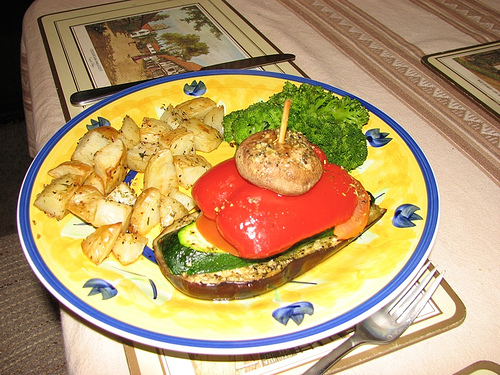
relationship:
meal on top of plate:
[34, 83, 387, 301] [17, 69, 440, 356]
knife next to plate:
[69, 53, 296, 109] [17, 69, 440, 356]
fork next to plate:
[304, 258, 447, 372] [17, 69, 440, 356]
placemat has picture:
[37, 5, 311, 124] [84, 5, 245, 86]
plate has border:
[17, 69, 440, 356] [19, 74, 441, 350]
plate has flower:
[17, 69, 440, 356] [185, 80, 206, 97]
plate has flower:
[17, 69, 440, 356] [367, 129, 392, 148]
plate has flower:
[17, 69, 440, 356] [394, 204, 423, 229]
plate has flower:
[17, 69, 440, 356] [274, 302, 315, 329]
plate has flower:
[17, 69, 440, 356] [84, 277, 119, 302]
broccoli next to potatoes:
[224, 81, 371, 173] [35, 97, 224, 268]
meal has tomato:
[34, 83, 387, 301] [196, 210, 240, 259]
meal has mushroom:
[34, 83, 387, 301] [234, 127, 323, 196]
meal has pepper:
[34, 83, 387, 301] [192, 144, 358, 261]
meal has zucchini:
[34, 83, 387, 301] [157, 219, 335, 278]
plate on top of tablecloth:
[17, 69, 440, 356] [22, 5, 497, 370]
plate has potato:
[17, 69, 440, 356] [176, 97, 219, 122]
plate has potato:
[17, 69, 440, 356] [139, 119, 172, 145]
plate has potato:
[17, 69, 440, 356] [144, 150, 179, 198]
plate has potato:
[17, 69, 440, 356] [92, 139, 129, 198]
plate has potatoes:
[17, 69, 440, 356] [80, 221, 123, 265]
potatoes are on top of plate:
[35, 97, 224, 268] [17, 69, 440, 356]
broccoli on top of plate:
[224, 81, 371, 173] [17, 69, 440, 356]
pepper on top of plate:
[192, 144, 358, 261] [17, 69, 440, 356]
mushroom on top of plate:
[234, 127, 323, 196] [17, 69, 440, 356]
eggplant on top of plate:
[152, 210, 387, 300] [17, 69, 440, 356]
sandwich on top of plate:
[154, 129, 388, 303] [17, 69, 440, 356]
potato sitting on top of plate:
[176, 97, 219, 122] [17, 69, 440, 356]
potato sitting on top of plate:
[139, 119, 172, 145] [17, 69, 440, 356]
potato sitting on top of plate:
[71, 122, 121, 168] [17, 69, 440, 356]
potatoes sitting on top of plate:
[80, 221, 123, 265] [17, 69, 440, 356]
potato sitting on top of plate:
[34, 178, 82, 223] [17, 69, 440, 356]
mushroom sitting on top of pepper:
[234, 127, 323, 196] [192, 144, 358, 261]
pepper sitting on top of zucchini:
[192, 144, 358, 261] [157, 219, 335, 278]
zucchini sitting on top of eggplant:
[157, 219, 335, 278] [152, 210, 387, 300]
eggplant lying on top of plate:
[152, 210, 387, 300] [17, 69, 440, 356]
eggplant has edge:
[152, 210, 387, 300] [154, 240, 349, 299]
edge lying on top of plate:
[154, 240, 349, 299] [17, 69, 440, 356]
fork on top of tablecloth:
[304, 258, 447, 372] [22, 5, 497, 370]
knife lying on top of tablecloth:
[69, 53, 296, 109] [22, 5, 497, 370]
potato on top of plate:
[176, 97, 219, 122] [17, 69, 440, 356]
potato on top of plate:
[144, 150, 179, 198] [17, 69, 440, 356]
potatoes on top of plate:
[80, 221, 123, 265] [17, 69, 440, 356]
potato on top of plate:
[92, 139, 129, 198] [17, 69, 440, 356]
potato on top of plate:
[71, 122, 121, 168] [17, 69, 440, 356]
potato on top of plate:
[34, 178, 82, 223] [17, 69, 440, 356]